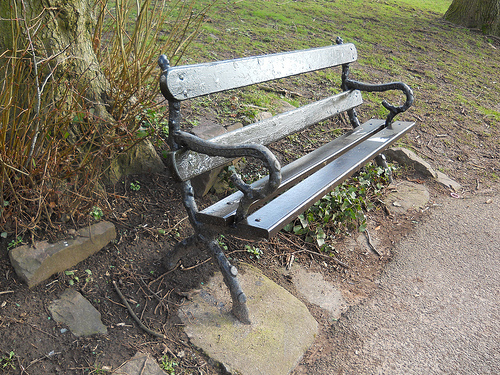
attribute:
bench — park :
[159, 41, 416, 236]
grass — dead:
[94, 2, 497, 202]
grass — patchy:
[328, 7, 498, 207]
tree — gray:
[6, 1, 142, 152]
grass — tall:
[1, 1, 208, 231]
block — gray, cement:
[177, 259, 317, 374]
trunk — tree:
[2, 51, 146, 221]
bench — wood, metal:
[157, 35, 409, 325]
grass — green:
[88, 1, 498, 182]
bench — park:
[123, 48, 464, 255]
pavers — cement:
[165, 248, 348, 370]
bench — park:
[104, 42, 442, 322]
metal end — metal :
[260, 146, 286, 177]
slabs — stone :
[181, 264, 321, 371]